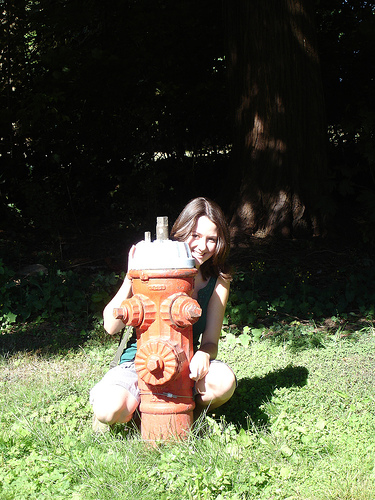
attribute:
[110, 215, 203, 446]
hydrant — orange, here, red, metallic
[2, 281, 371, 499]
grass — green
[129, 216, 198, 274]
cap — white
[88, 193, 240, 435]
girl — pretty, smiling, peaking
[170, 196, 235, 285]
hair — long, brown, brunette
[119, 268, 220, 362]
top — green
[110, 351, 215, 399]
shorts — brown, purple, blue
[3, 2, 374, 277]
woods — behind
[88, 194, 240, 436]
lady — here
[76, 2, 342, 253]
tree — thick, here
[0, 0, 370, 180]
leaves — small, green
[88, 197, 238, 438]
woman — posing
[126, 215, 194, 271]
top — white, silver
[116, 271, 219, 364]
shirt — blue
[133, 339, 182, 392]
valve — orange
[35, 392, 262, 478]
section of grass — small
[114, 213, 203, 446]
extinguisher — large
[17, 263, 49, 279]
rock — large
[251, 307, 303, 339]
stick — small